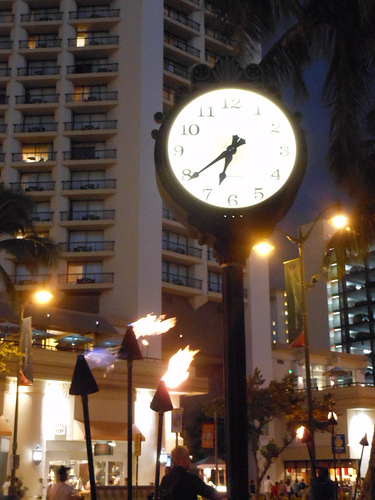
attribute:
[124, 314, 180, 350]
gust — sideways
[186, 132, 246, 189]
hands — black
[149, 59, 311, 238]
clock — illuminated, large, lit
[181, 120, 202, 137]
number — black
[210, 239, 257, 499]
pole — black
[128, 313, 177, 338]
flame — fire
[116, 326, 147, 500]
torch — tall, burning, lit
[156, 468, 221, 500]
shirt — black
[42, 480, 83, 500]
shirt — white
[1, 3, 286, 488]
building — large, tall, a hotel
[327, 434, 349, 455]
sign — blue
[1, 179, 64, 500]
tree — large, palm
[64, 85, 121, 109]
balcony — gated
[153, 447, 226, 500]
person — walking, wearing black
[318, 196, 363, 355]
street light — on, turned on, glowing, double globed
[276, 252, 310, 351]
flag — orange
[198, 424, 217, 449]
banner — orange, hanging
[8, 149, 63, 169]
balcony — lit up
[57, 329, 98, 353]
umbrella — green